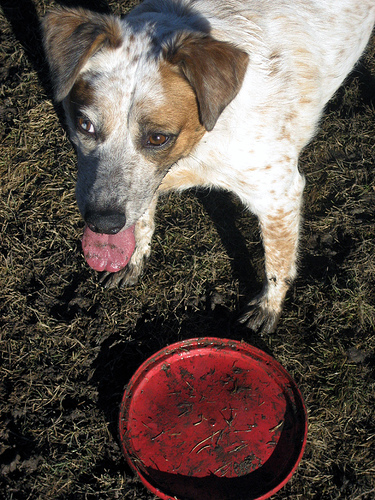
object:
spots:
[268, 49, 320, 141]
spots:
[261, 207, 296, 278]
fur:
[180, 130, 226, 187]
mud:
[0, 0, 373, 495]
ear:
[171, 41, 250, 131]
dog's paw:
[235, 297, 283, 340]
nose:
[84, 211, 126, 234]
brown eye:
[146, 134, 170, 147]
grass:
[320, 379, 363, 451]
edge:
[117, 400, 128, 461]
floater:
[117, 339, 309, 500]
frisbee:
[116, 332, 311, 490]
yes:
[98, 259, 285, 338]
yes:
[32, 1, 373, 335]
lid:
[122, 335, 302, 497]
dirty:
[119, 338, 305, 499]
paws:
[99, 271, 141, 291]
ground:
[9, 303, 142, 367]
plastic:
[158, 309, 256, 388]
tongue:
[82, 227, 135, 272]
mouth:
[81, 221, 137, 289]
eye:
[73, 111, 96, 135]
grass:
[0, 362, 73, 498]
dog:
[50, 0, 368, 333]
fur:
[116, 29, 167, 108]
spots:
[125, 35, 140, 64]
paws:
[104, 252, 277, 325]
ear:
[42, 17, 120, 100]